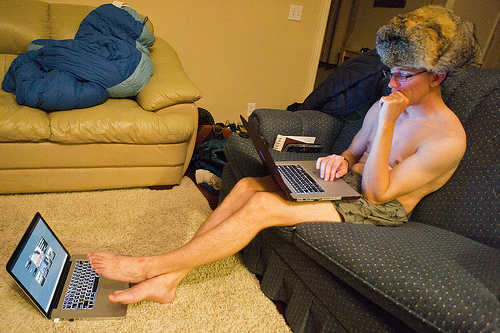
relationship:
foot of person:
[88, 249, 153, 284] [87, 41, 466, 302]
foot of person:
[88, 249, 153, 284] [86, 2, 466, 311]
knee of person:
[231, 174, 278, 221] [84, 66, 485, 302]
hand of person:
[307, 148, 353, 183] [86, 2, 466, 311]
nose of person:
[385, 74, 402, 93] [86, 2, 466, 311]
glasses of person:
[378, 66, 427, 80] [84, 66, 485, 302]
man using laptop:
[86, 6, 482, 304] [241, 113, 357, 203]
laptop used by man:
[237, 109, 362, 205] [85, 68, 468, 306]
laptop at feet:
[237, 109, 362, 205] [85, 247, 171, 307]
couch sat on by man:
[3, 2, 190, 184] [85, 68, 468, 306]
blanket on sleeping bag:
[0, 1, 154, 111] [102, 8, 156, 117]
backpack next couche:
[198, 117, 236, 142] [4, 28, 200, 200]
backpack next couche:
[198, 117, 236, 142] [213, 46, 493, 326]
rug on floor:
[2, 190, 282, 331] [1, 183, 270, 332]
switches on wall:
[286, 2, 309, 25] [206, 1, 324, 108]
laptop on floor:
[237, 109, 362, 205] [6, 186, 235, 324]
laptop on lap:
[237, 109, 362, 205] [239, 181, 368, 228]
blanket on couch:
[9, 1, 172, 116] [2, 10, 200, 200]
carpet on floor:
[2, 191, 284, 330] [2, 197, 247, 326]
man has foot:
[86, 6, 482, 304] [88, 249, 153, 284]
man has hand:
[86, 6, 482, 304] [307, 148, 353, 183]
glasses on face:
[378, 66, 427, 80] [382, 61, 423, 101]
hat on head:
[373, 9, 477, 69] [373, 6, 463, 104]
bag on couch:
[5, 4, 162, 118] [2, 10, 200, 200]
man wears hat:
[290, 1, 480, 235] [373, 9, 477, 69]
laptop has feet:
[237, 109, 362, 205] [79, 239, 186, 313]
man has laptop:
[86, 6, 482, 304] [266, 155, 364, 209]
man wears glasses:
[315, 8, 475, 229] [378, 66, 427, 80]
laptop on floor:
[7, 209, 128, 319] [0, 175, 293, 331]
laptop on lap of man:
[237, 109, 362, 205] [86, 6, 482, 304]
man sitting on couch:
[86, 6, 482, 304] [215, 63, 497, 330]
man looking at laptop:
[86, 6, 482, 304] [237, 109, 362, 205]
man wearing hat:
[86, 6, 482, 304] [373, 9, 477, 69]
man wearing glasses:
[86, 6, 482, 304] [382, 64, 429, 85]